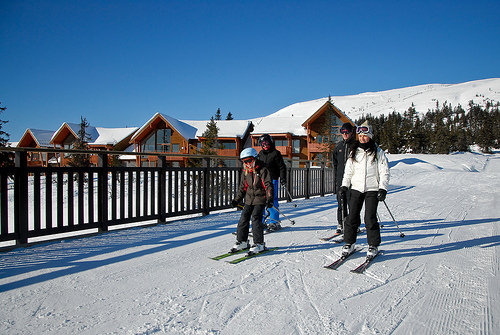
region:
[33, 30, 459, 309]
this is at ski resort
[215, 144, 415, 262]
these people are skiing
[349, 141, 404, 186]
the girl has a white jacket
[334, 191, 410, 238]
the girl has a black pants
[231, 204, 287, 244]
the person's pants are black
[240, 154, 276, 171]
the person is wearing a helmet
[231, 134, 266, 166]
the helmet is light blue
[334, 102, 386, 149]
the girl has goggles on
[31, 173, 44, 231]
brown wooden fence board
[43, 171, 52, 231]
brown wooden fence board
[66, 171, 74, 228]
brown wooden fence board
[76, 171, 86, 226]
brown wooden fence board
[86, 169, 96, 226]
brown wooden fence board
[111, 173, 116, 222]
brown wooden fence board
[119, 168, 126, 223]
brown wooden fence board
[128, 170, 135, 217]
brown wooden fence board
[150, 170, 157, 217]
brown wooden fence board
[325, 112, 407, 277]
person on skis.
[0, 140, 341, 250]
Fence beside the skiers.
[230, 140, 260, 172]
White helmet on the head.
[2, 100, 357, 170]
Lodge in the background.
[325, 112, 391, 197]
white jacket on woman.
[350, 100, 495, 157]
Trees in the background.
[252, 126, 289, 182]
black jacket on person.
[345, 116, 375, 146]
goggles on the hat.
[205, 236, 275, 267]
Green skis on the feet.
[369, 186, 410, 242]
Ski pole in the hand.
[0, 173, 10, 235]
brown wooden fence board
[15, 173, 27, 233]
brown wooden fence board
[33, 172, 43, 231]
brown wooden fence board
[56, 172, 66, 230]
brown wooden fence board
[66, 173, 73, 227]
brown wooden fence board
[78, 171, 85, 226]
brown wooden fence board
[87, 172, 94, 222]
brown wooden fence board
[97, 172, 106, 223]
brown wooden fence board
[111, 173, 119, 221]
brown wooden fence board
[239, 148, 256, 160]
guy wearing blue color helmet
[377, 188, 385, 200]
woman wearing black color gloves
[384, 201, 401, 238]
woman holding skiing road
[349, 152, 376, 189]
woman wearing white jacket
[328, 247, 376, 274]
woman skating on snow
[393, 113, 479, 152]
trees visible at background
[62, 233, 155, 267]
shadow of railing falling on ground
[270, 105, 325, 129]
roof of houses covered with snow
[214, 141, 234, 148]
window of houses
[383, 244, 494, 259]
shadow of woman falling on snow